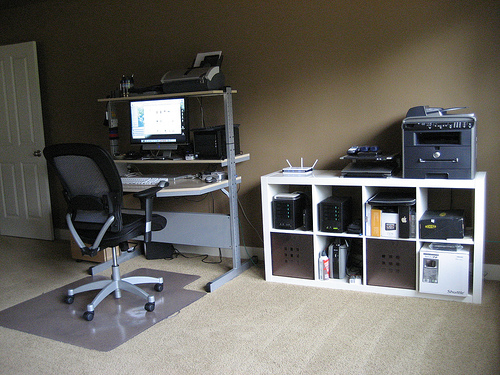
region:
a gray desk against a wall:
[85, 88, 257, 291]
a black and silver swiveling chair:
[42, 142, 166, 319]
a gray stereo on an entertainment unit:
[403, 115, 475, 179]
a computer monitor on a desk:
[128, 98, 189, 159]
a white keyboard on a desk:
[118, 176, 165, 186]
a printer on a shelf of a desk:
[161, 62, 225, 89]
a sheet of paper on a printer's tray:
[193, 48, 221, 70]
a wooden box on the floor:
[70, 234, 119, 262]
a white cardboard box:
[419, 242, 469, 297]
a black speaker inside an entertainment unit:
[317, 193, 348, 233]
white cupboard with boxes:
[256, 168, 486, 305]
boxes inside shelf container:
[258, 167, 483, 302]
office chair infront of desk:
[40, 144, 165, 325]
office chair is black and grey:
[43, 146, 167, 318]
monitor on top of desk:
[130, 102, 190, 139]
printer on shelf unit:
[404, 100, 476, 180]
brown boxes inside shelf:
[366, 237, 418, 289]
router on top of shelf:
[282, 160, 317, 174]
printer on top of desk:
[158, 50, 225, 92]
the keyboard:
[125, 175, 152, 186]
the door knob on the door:
[30, 148, 45, 163]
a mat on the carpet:
[87, 325, 108, 346]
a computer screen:
[127, 100, 182, 132]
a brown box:
[367, 244, 416, 288]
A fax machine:
[399, 104, 481, 178]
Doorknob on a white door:
[32, 148, 41, 159]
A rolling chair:
[37, 138, 168, 315]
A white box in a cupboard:
[420, 243, 471, 298]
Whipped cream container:
[315, 248, 331, 279]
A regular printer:
[157, 48, 227, 93]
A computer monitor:
[127, 97, 189, 149]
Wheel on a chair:
[82, 310, 94, 322]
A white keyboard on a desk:
[118, 175, 168, 185]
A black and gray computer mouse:
[201, 172, 216, 182]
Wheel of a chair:
[141, 298, 158, 316]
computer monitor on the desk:
[115, 98, 194, 153]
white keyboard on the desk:
[111, 156, 166, 193]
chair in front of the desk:
[34, 133, 174, 337]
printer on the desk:
[158, 49, 227, 92]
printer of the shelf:
[389, 94, 489, 189]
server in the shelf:
[313, 191, 345, 235]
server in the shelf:
[271, 197, 297, 229]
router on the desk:
[276, 152, 316, 177]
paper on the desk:
[416, 212, 468, 242]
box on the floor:
[57, 218, 117, 268]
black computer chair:
[43, 135, 174, 328]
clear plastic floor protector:
[2, 259, 218, 359]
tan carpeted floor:
[4, 230, 497, 373]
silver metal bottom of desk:
[87, 200, 259, 292]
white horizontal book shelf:
[256, 170, 486, 310]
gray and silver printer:
[395, 95, 481, 187]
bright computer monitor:
[124, 90, 186, 155]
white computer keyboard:
[110, 173, 167, 191]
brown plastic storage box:
[270, 230, 317, 280]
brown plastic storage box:
[362, 235, 419, 292]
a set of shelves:
[259, 159, 483, 305]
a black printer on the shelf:
[390, 98, 490, 185]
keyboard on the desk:
[115, 163, 165, 190]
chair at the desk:
[35, 129, 170, 316]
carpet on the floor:
[215, 293, 397, 373]